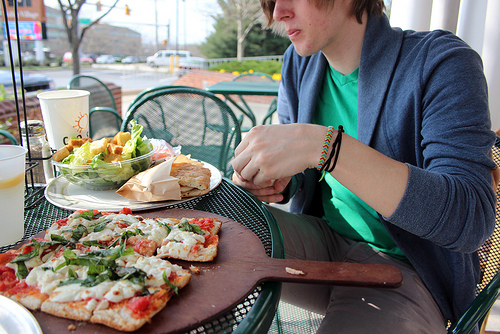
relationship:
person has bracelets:
[225, 0, 495, 334] [320, 122, 349, 172]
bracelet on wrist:
[320, 123, 344, 174] [294, 123, 355, 173]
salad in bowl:
[46, 121, 161, 188] [49, 148, 171, 188]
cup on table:
[33, 87, 96, 142] [226, 196, 258, 218]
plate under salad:
[40, 152, 230, 214] [51, 117, 155, 182]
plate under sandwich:
[40, 152, 230, 214] [117, 153, 215, 205]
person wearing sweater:
[225, 0, 495, 334] [264, 7, 499, 315]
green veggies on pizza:
[19, 227, 148, 302] [0, 207, 219, 325]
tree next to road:
[57, 3, 99, 97] [32, 58, 214, 91]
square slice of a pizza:
[159, 210, 224, 265] [0, 187, 245, 329]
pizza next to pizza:
[0, 208, 223, 330] [163, 209, 232, 267]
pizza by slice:
[0, 208, 223, 330] [131, 260, 186, 307]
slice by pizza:
[131, 260, 186, 307] [0, 208, 223, 330]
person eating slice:
[225, 0, 495, 334] [131, 260, 186, 307]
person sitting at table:
[225, 0, 495, 334] [3, 134, 276, 332]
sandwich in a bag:
[117, 153, 215, 205] [114, 156, 184, 204]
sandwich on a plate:
[117, 153, 215, 205] [44, 154, 224, 211]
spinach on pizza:
[62, 243, 132, 285] [2, 199, 212, 322]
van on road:
[137, 27, 213, 115] [130, 24, 215, 86]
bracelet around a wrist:
[316, 122, 336, 182] [312, 121, 350, 180]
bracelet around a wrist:
[319, 123, 346, 185] [312, 121, 350, 180]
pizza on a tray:
[23, 180, 240, 324] [26, 206, 406, 331]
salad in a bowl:
[46, 121, 156, 191] [49, 134, 156, 189]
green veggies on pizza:
[65, 237, 134, 278] [4, 212, 228, 322]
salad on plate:
[46, 121, 156, 191] [44, 157, 222, 214]